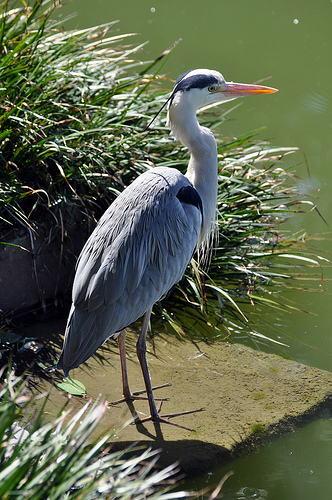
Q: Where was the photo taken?
A: It was taken at the shore.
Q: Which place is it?
A: It is a shore.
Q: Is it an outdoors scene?
A: Yes, it is outdoors.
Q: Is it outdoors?
A: Yes, it is outdoors.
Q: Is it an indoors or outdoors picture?
A: It is outdoors.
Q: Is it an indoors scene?
A: No, it is outdoors.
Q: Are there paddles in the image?
A: No, there are no paddles.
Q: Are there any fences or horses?
A: No, there are no fences or horses.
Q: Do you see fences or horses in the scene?
A: No, there are no fences or horses.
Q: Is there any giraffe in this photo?
A: No, there are no giraffes.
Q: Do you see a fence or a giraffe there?
A: No, there are no giraffes or fences.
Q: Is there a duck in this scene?
A: No, there are no ducks.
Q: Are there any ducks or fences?
A: No, there are no ducks or fences.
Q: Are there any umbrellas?
A: No, there are no umbrellas.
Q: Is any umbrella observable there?
A: No, there are no umbrellas.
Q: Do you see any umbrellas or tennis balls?
A: No, there are no umbrellas or tennis balls.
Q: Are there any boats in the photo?
A: No, there are no boats.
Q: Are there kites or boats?
A: No, there are no boats or kites.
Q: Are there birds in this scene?
A: Yes, there is a bird.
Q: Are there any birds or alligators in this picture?
A: Yes, there is a bird.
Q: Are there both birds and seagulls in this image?
A: No, there is a bird but no seagulls.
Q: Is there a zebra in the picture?
A: No, there are no zebras.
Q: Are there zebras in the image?
A: No, there are no zebras.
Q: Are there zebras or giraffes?
A: No, there are no zebras or giraffes.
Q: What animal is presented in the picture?
A: The animal is a bird.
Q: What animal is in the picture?
A: The animal is a bird.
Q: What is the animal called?
A: The animal is a bird.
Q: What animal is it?
A: The animal is a bird.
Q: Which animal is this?
A: This is a bird.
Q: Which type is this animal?
A: This is a bird.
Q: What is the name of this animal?
A: This is a bird.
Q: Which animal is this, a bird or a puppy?
A: This is a bird.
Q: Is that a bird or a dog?
A: That is a bird.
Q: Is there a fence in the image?
A: No, there are no fences.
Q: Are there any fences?
A: No, there are no fences.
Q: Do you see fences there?
A: No, there are no fences.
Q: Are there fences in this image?
A: No, there are no fences.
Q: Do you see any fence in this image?
A: No, there are no fences.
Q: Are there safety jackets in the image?
A: No, there are no safety jackets.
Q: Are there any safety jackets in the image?
A: No, there are no safety jackets.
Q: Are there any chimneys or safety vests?
A: No, there are no safety vests or chimneys.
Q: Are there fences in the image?
A: No, there are no fences.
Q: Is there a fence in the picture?
A: No, there are no fences.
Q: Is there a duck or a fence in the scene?
A: No, there are no fences or ducks.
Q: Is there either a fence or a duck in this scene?
A: No, there are no fences or ducks.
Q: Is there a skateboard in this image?
A: No, there are no skateboards.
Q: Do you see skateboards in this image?
A: No, there are no skateboards.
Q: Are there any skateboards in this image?
A: No, there are no skateboards.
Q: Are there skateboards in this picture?
A: No, there are no skateboards.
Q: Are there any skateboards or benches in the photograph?
A: No, there are no skateboards or benches.